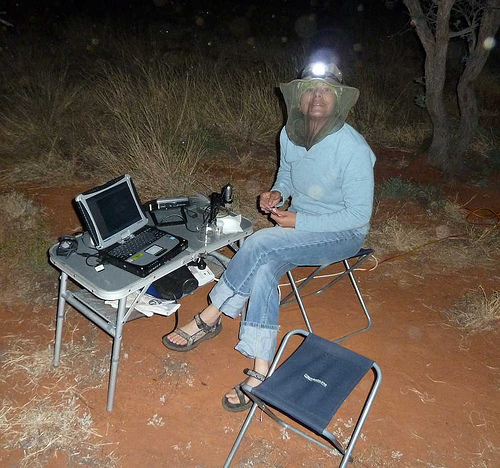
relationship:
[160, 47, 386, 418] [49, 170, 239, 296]
woman has equipment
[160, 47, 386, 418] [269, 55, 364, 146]
woman wearing netting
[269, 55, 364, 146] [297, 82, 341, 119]
netting on head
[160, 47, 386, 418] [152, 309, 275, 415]
woman wearing sandals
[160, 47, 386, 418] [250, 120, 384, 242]
woman wearing shirt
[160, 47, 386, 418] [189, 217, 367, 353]
woman wearing jeans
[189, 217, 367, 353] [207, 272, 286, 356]
jeans have cuffs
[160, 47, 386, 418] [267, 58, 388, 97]
woman wearing hat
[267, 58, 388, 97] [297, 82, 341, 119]
hat on head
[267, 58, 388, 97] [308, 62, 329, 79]
hat has light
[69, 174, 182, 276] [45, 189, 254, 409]
laptop on table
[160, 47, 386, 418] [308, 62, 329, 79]
woman has light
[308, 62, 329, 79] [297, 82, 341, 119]
light on head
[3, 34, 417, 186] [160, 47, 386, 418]
grass behind woman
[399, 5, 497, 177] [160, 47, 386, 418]
tree behind woman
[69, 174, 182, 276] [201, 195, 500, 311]
laptop has power cord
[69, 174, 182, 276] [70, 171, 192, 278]
laptop in laptop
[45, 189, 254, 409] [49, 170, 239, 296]
table has equipment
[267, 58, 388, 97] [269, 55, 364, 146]
hat has netting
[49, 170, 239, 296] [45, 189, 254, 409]
equipment on table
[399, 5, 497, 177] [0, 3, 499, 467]
tree in outside